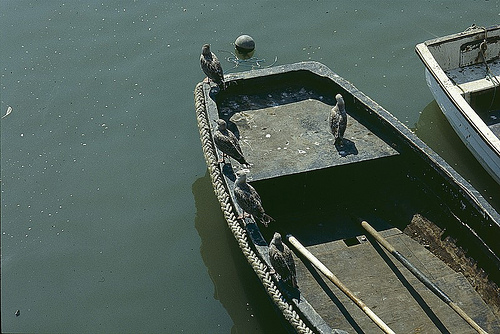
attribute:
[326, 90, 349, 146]
bird — large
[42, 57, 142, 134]
ripples — colored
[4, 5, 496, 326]
ocean — green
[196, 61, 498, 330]
boat — white, black, brown colored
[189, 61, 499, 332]
rowboat — wooden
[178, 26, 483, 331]
boat — brown colored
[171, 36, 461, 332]
boat — brown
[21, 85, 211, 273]
water — calm